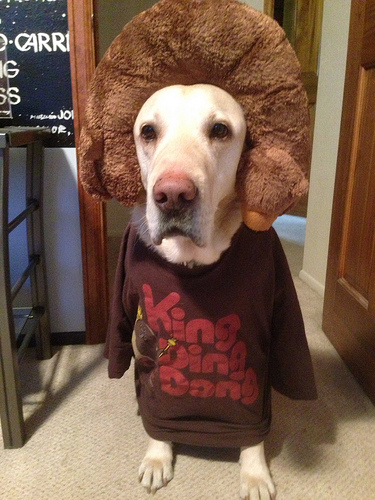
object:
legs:
[25, 145, 56, 362]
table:
[0, 126, 57, 451]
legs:
[2, 153, 27, 451]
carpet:
[3, 238, 375, 496]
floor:
[2, 205, 374, 498]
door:
[322, 0, 375, 400]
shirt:
[103, 215, 319, 448]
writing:
[137, 282, 258, 403]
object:
[79, 0, 311, 231]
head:
[133, 83, 244, 248]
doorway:
[93, 2, 343, 336]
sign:
[0, 0, 75, 147]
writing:
[0, 33, 72, 135]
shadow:
[261, 343, 371, 477]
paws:
[237, 466, 280, 500]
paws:
[134, 448, 177, 494]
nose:
[150, 167, 200, 212]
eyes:
[204, 120, 233, 143]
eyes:
[134, 120, 158, 144]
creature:
[128, 82, 277, 499]